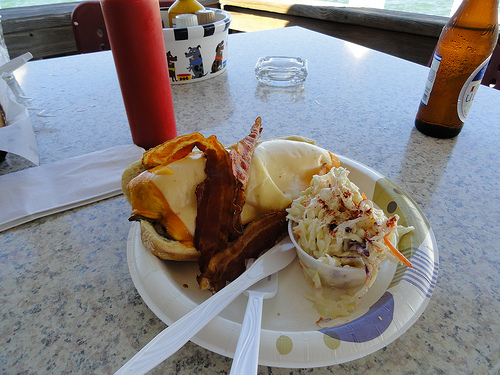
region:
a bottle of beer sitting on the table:
[415, 0, 499, 139]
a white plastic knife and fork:
[111, 235, 297, 373]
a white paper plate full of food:
[124, 150, 439, 367]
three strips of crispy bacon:
[143, 115, 288, 292]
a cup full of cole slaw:
[285, 166, 409, 316]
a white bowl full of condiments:
[159, 1, 230, 84]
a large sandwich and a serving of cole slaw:
[120, 117, 410, 319]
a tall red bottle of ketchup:
[97, 1, 177, 146]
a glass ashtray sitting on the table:
[252, 52, 307, 88]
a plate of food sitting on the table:
[119, 115, 439, 370]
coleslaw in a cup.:
[282, 164, 412, 296]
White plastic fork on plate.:
[223, 251, 288, 373]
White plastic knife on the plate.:
[112, 233, 294, 373]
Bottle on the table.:
[409, 0, 499, 141]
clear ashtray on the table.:
[251, 50, 312, 90]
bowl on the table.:
[160, 0, 234, 87]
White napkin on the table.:
[2, 140, 149, 236]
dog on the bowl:
[183, 40, 208, 82]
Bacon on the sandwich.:
[136, 111, 286, 287]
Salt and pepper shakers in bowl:
[171, 5, 220, 30]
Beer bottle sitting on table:
[410, 1, 499, 145]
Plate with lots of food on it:
[118, 124, 443, 365]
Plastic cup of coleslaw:
[286, 166, 418, 292]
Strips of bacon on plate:
[142, 120, 272, 255]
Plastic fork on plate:
[242, 254, 282, 374]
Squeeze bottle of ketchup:
[95, 2, 182, 139]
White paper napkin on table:
[1, 146, 131, 221]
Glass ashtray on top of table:
[254, 50, 309, 88]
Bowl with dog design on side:
[162, 1, 236, 84]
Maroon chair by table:
[67, 1, 109, 54]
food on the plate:
[107, 128, 404, 329]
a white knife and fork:
[115, 241, 292, 372]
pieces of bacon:
[149, 118, 274, 284]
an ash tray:
[256, 55, 306, 83]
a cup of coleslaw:
[288, 167, 389, 291]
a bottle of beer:
[414, 0, 499, 139]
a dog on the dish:
[184, 42, 208, 80]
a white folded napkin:
[1, 143, 147, 227]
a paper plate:
[127, 143, 439, 369]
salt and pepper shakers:
[174, 10, 214, 26]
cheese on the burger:
[152, 145, 286, 243]